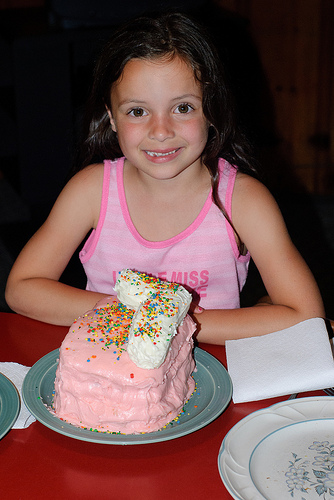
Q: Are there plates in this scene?
A: Yes, there is a plate.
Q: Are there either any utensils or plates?
A: Yes, there is a plate.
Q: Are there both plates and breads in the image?
A: No, there is a plate but no breads.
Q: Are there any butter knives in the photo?
A: No, there are no butter knives.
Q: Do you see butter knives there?
A: No, there are no butter knives.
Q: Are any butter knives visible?
A: No, there are no butter knives.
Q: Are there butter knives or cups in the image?
A: No, there are no butter knives or cups.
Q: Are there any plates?
A: Yes, there is a plate.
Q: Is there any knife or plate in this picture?
A: Yes, there is a plate.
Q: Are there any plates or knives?
A: Yes, there is a plate.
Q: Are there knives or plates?
A: Yes, there is a plate.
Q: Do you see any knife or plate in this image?
A: Yes, there is a plate.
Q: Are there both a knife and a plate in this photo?
A: No, there is a plate but no knives.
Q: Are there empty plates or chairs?
A: Yes, there is an empty plate.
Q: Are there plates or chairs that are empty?
A: Yes, the plate is empty.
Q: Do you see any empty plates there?
A: Yes, there is an empty plate.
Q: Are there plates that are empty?
A: Yes, there is a plate that is empty.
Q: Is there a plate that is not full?
A: Yes, there is a empty plate.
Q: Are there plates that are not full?
A: Yes, there is a empty plate.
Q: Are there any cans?
A: No, there are no cans.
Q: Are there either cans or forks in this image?
A: No, there are no cans or forks.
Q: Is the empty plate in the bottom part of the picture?
A: Yes, the plate is in the bottom of the image.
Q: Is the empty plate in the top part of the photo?
A: No, the plate is in the bottom of the image.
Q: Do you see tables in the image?
A: Yes, there is a table.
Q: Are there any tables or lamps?
A: Yes, there is a table.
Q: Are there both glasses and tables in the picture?
A: No, there is a table but no glasses.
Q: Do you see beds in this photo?
A: No, there are no beds.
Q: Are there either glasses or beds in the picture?
A: No, there are no beds or glasses.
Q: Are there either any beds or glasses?
A: No, there are no beds or glasses.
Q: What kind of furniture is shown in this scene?
A: The furniture is a table.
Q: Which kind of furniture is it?
A: The piece of furniture is a table.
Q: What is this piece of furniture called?
A: This is a table.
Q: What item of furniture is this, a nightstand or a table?
A: This is a table.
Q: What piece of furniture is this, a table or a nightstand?
A: This is a table.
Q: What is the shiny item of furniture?
A: The piece of furniture is a table.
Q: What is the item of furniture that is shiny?
A: The piece of furniture is a table.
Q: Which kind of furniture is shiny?
A: The furniture is a table.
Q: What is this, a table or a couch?
A: This is a table.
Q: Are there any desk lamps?
A: No, there are no desk lamps.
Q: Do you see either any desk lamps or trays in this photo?
A: No, there are no desk lamps or trays.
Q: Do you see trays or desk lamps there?
A: No, there are no desk lamps or trays.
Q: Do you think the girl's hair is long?
A: Yes, the hair is long.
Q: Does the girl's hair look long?
A: Yes, the hair is long.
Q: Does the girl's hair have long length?
A: Yes, the hair is long.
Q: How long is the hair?
A: The hair is long.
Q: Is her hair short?
A: No, the hair is long.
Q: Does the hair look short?
A: No, the hair is long.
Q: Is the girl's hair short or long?
A: The hair is long.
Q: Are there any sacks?
A: No, there are no sacks.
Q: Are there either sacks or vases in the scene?
A: No, there are no sacks or vases.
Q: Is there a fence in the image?
A: No, there are no fences.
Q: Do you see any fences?
A: No, there are no fences.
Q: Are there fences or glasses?
A: No, there are no fences or glasses.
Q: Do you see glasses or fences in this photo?
A: No, there are no fences or glasses.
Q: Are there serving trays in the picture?
A: No, there are no serving trays.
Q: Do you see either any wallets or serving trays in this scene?
A: No, there are no serving trays or wallets.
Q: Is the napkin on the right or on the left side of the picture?
A: The napkin is on the right of the image.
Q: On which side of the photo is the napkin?
A: The napkin is on the right of the image.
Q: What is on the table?
A: The napkin is on the table.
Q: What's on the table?
A: The napkin is on the table.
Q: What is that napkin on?
A: The napkin is on the table.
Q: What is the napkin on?
A: The napkin is on the table.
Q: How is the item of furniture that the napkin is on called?
A: The piece of furniture is a table.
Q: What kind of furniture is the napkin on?
A: The napkin is on the table.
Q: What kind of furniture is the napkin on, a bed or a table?
A: The napkin is on a table.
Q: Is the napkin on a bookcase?
A: No, the napkin is on the table.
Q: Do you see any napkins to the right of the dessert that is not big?
A: Yes, there is a napkin to the right of the cake.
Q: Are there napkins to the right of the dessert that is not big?
A: Yes, there is a napkin to the right of the cake.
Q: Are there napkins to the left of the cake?
A: No, the napkin is to the right of the cake.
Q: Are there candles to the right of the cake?
A: No, there is a napkin to the right of the cake.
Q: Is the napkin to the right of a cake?
A: Yes, the napkin is to the right of a cake.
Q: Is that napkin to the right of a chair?
A: No, the napkin is to the right of a cake.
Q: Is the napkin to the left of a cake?
A: No, the napkin is to the right of a cake.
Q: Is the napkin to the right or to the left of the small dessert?
A: The napkin is to the right of the cake.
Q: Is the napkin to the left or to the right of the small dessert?
A: The napkin is to the right of the cake.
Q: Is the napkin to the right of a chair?
A: No, the napkin is to the right of the plate.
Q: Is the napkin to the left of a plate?
A: No, the napkin is to the right of a plate.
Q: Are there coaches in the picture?
A: No, there are no coaches.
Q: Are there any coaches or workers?
A: No, there are no coaches or workers.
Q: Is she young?
A: Yes, the girl is young.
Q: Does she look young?
A: Yes, the girl is young.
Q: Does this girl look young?
A: Yes, the girl is young.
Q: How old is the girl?
A: The girl is young.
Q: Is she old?
A: No, the girl is young.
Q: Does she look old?
A: No, the girl is young.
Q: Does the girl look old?
A: No, the girl is young.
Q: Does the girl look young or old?
A: The girl is young.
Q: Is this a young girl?
A: Yes, this is a young girl.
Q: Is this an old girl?
A: No, this is a young girl.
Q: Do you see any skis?
A: No, there are no skis.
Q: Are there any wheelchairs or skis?
A: No, there are no skis or wheelchairs.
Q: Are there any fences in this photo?
A: No, there are no fences.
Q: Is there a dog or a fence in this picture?
A: No, there are no fences or dogs.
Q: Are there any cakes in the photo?
A: Yes, there is a cake.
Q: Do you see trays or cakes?
A: Yes, there is a cake.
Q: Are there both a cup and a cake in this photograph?
A: No, there is a cake but no cups.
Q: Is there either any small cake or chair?
A: Yes, there is a small cake.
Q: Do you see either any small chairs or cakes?
A: Yes, there is a small cake.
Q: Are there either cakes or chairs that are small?
A: Yes, the cake is small.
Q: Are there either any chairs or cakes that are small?
A: Yes, the cake is small.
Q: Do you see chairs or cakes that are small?
A: Yes, the cake is small.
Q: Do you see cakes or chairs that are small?
A: Yes, the cake is small.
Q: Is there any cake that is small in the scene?
A: Yes, there is a small cake.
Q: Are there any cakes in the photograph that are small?
A: Yes, there is a cake that is small.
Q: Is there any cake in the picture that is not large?
A: Yes, there is a small cake.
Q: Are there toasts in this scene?
A: No, there are no toasts.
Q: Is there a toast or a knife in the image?
A: No, there are no toasts or knives.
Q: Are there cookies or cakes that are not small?
A: No, there is a cake but it is small.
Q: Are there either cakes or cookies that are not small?
A: No, there is a cake but it is small.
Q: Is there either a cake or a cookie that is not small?
A: No, there is a cake but it is small.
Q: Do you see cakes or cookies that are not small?
A: No, there is a cake but it is small.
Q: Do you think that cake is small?
A: Yes, the cake is small.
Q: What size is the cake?
A: The cake is small.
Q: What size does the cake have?
A: The cake has small size.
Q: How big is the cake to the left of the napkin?
A: The cake is small.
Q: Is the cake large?
A: No, the cake is small.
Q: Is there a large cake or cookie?
A: No, there is a cake but it is small.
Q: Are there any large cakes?
A: No, there is a cake but it is small.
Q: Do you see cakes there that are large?
A: No, there is a cake but it is small.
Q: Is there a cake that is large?
A: No, there is a cake but it is small.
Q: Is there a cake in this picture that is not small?
A: No, there is a cake but it is small.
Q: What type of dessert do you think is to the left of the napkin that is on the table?
A: The dessert is a cake.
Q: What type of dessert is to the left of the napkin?
A: The dessert is a cake.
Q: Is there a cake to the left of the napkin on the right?
A: Yes, there is a cake to the left of the napkin.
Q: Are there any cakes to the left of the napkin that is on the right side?
A: Yes, there is a cake to the left of the napkin.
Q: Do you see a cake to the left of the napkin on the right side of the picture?
A: Yes, there is a cake to the left of the napkin.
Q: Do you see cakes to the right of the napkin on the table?
A: No, the cake is to the left of the napkin.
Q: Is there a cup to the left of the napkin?
A: No, there is a cake to the left of the napkin.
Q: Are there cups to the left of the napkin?
A: No, there is a cake to the left of the napkin.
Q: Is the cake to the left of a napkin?
A: Yes, the cake is to the left of a napkin.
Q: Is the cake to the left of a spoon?
A: No, the cake is to the left of a napkin.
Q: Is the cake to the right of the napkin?
A: No, the cake is to the left of the napkin.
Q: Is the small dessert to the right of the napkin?
A: No, the cake is to the left of the napkin.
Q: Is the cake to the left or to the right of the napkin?
A: The cake is to the left of the napkin.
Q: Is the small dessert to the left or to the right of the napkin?
A: The cake is to the left of the napkin.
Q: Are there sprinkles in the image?
A: Yes, there are sprinkles.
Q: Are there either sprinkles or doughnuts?
A: Yes, there are sprinkles.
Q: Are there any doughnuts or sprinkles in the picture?
A: Yes, there are sprinkles.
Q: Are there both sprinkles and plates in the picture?
A: Yes, there are both sprinkles and a plate.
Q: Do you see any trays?
A: No, there are no trays.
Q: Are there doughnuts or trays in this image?
A: No, there are no trays or doughnuts.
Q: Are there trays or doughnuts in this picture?
A: No, there are no trays or doughnuts.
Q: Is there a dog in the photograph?
A: No, there are no dogs.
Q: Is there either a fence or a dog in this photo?
A: No, there are no dogs or fences.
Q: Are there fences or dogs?
A: No, there are no dogs or fences.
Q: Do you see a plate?
A: Yes, there is a plate.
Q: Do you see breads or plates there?
A: Yes, there is a plate.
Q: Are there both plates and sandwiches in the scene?
A: No, there is a plate but no sandwiches.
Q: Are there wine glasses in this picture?
A: No, there are no wine glasses.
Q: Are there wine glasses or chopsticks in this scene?
A: No, there are no wine glasses or chopsticks.